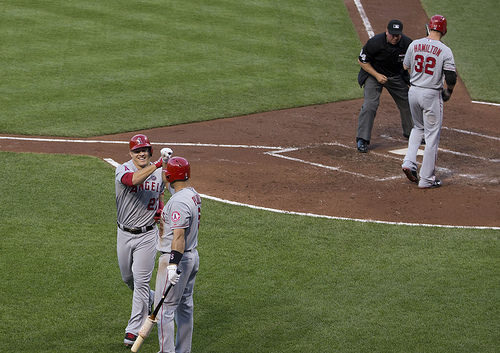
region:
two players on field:
[74, 92, 243, 272]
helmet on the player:
[124, 121, 156, 164]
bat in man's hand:
[105, 261, 190, 352]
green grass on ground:
[220, 242, 329, 319]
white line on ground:
[212, 120, 318, 174]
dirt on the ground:
[236, 151, 297, 201]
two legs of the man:
[381, 101, 458, 187]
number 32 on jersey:
[397, 40, 449, 82]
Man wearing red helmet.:
[164, 150, 196, 195]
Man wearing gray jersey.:
[155, 209, 214, 246]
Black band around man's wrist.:
[165, 247, 194, 269]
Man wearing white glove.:
[165, 266, 200, 287]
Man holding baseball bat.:
[146, 260, 210, 315]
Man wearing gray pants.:
[154, 265, 199, 327]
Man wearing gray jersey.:
[113, 162, 161, 215]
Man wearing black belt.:
[121, 211, 166, 254]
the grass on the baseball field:
[341, 270, 413, 326]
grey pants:
[163, 304, 195, 351]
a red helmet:
[166, 157, 189, 182]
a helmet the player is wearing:
[169, 157, 186, 179]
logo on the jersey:
[133, 178, 163, 193]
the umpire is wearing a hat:
[389, 22, 401, 35]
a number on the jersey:
[413, 53, 438, 82]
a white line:
[335, 210, 368, 225]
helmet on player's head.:
[124, 130, 146, 150]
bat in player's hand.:
[149, 289, 169, 324]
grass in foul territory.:
[37, 195, 62, 227]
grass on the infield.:
[102, 41, 145, 67]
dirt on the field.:
[276, 183, 307, 196]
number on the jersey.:
[412, 57, 436, 77]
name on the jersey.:
[413, 44, 440, 52]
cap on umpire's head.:
[391, 20, 403, 34]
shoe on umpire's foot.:
[351, 137, 367, 156]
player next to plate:
[351, 9, 467, 159]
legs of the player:
[379, 107, 456, 183]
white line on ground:
[215, 121, 297, 186]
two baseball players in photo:
[68, 97, 228, 256]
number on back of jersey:
[401, 52, 444, 83]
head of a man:
[368, 9, 412, 53]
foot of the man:
[336, 128, 377, 175]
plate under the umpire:
[381, 130, 431, 175]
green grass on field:
[93, 12, 240, 101]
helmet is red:
[160, 153, 192, 182]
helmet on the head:
[166, 158, 201, 172]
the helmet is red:
[128, 133, 147, 149]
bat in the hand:
[130, 287, 169, 347]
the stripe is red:
[155, 335, 165, 340]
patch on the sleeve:
[170, 203, 180, 223]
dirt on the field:
[257, 173, 314, 189]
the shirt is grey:
[125, 206, 148, 221]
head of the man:
[126, 148, 155, 168]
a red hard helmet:
[124, 131, 132, 160]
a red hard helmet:
[429, 10, 444, 28]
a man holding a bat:
[155, 193, 215, 351]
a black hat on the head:
[374, 16, 404, 41]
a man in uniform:
[152, 174, 192, 339]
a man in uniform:
[93, 141, 168, 287]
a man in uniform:
[402, 23, 477, 173]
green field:
[339, 269, 404, 330]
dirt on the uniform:
[156, 214, 168, 240]